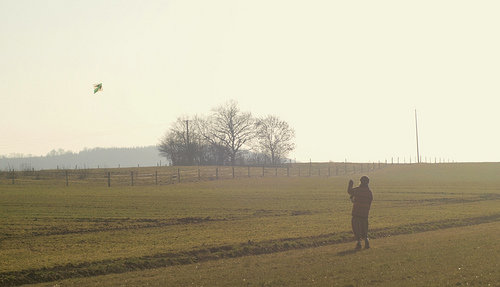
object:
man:
[345, 175, 372, 249]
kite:
[91, 81, 103, 94]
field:
[3, 163, 498, 283]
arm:
[345, 181, 360, 194]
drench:
[27, 203, 499, 280]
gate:
[29, 159, 477, 171]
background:
[18, 116, 474, 204]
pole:
[412, 109, 420, 163]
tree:
[154, 100, 299, 168]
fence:
[0, 155, 458, 187]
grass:
[21, 174, 490, 275]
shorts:
[345, 214, 376, 240]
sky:
[3, 4, 498, 171]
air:
[42, 41, 430, 173]